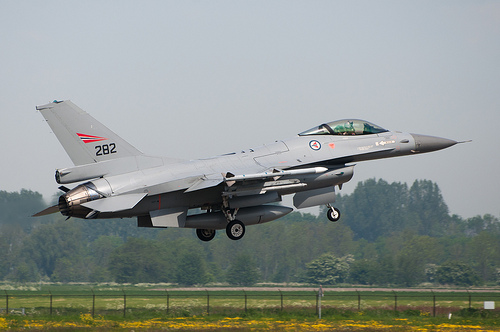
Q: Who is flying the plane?
A: A pilot.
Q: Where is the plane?
A: In the air.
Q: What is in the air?
A: A plane.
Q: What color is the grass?
A: Green.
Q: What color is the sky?
A: Blue.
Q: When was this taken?
A: During the day.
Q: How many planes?
A: One.